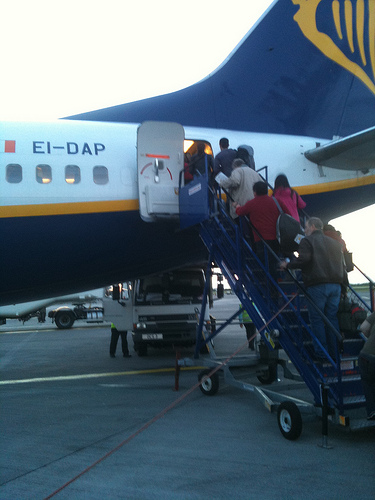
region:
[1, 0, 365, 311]
a light blue and orange airplane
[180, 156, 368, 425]
a dark blue stair case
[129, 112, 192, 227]
an open airplane hatch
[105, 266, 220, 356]
a large white truck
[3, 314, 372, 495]
grey concrete paved tarmac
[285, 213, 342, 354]
passenger standing on stairs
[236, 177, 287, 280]
passenger standing on stairs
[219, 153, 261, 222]
passenger standing on stairs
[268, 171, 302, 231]
passenger standing on stairs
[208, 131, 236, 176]
passenger standing on stairs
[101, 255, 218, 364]
A white truck.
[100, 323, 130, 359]
The person is wearing black pants.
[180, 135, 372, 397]
People are boarding the plane.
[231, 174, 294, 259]
The person is carrying a bag.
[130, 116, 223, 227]
The plane door is open.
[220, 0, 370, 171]
The plane's vertical stabilizer has a picture of a harp on it.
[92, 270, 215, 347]
The truck's door is open.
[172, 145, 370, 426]
Passenger boarding stairs.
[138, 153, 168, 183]
The door handle.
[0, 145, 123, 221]
The airplane's windows.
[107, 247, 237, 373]
a white airport van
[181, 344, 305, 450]
two wheels on a cart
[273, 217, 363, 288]
a man in a black jacket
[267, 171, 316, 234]
woman in a pink coat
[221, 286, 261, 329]
a green jacket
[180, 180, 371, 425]
a blue staircase to the plane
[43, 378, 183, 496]
a red cord on the ground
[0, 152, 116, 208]
windows for the seats on the plane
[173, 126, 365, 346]
people boarding the plane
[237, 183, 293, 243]
a woman in a red sweater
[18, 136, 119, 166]
EL-DAP in blue text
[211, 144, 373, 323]
people walking up stairs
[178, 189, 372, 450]
rolling metal blue stairs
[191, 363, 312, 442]
black and white wheels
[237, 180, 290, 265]
woman wearing red jacket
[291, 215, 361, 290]
man wearing brown jacket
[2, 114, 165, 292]
white blue and yellow plane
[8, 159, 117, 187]
windows on a plane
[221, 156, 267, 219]
man wearing tan jacket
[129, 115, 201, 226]
door of plane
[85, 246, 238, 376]
small white delivery van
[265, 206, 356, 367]
man in jeans and jacket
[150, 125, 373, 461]
airplane loading ramp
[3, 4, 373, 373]
passengers get on a plane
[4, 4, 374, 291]
tail of a large plane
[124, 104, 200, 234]
rear exit door of plane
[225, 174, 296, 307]
woman in red shirt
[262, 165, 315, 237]
girl in pink shirt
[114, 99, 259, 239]
emergency exit for plane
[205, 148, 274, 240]
man in a tan jacket